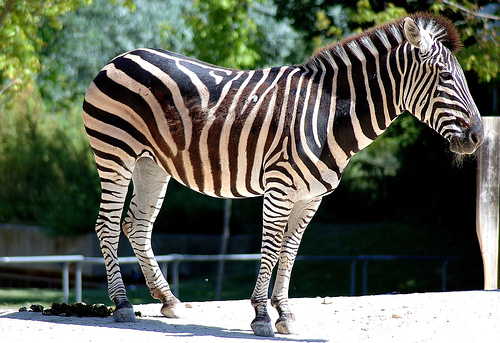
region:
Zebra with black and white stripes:
[79, 8, 486, 339]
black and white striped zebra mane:
[296, 9, 470, 74]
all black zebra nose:
[448, 116, 488, 154]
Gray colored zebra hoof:
[248, 319, 275, 335]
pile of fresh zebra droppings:
[17, 296, 111, 318]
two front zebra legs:
[241, 193, 322, 336]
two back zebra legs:
[88, 156, 192, 321]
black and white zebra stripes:
[106, 67, 227, 127]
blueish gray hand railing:
[0, 252, 84, 299]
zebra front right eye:
[439, 70, 453, 80]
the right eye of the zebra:
[431, 66, 454, 82]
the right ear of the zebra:
[397, 14, 428, 56]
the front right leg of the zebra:
[245, 159, 296, 341]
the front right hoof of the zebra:
[246, 310, 276, 341]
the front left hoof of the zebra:
[272, 310, 304, 341]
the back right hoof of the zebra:
[105, 292, 137, 324]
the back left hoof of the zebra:
[152, 291, 192, 323]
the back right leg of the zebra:
[80, 128, 162, 320]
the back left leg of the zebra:
[120, 140, 200, 320]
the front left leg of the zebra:
[267, 179, 325, 337]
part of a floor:
[333, 291, 363, 331]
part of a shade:
[180, 315, 205, 335]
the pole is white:
[5, 244, 76, 276]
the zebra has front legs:
[247, 212, 297, 337]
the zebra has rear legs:
[89, 177, 183, 329]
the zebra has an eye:
[432, 58, 456, 85]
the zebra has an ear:
[389, 9, 428, 39]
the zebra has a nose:
[463, 122, 482, 152]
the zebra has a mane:
[312, 35, 384, 54]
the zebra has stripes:
[175, 103, 284, 154]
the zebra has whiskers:
[453, 148, 465, 165]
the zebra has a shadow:
[157, 319, 214, 333]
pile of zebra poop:
[15, 294, 115, 321]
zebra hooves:
[109, 295, 309, 340]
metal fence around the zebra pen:
[0, 245, 496, 292]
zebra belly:
[157, 134, 273, 211]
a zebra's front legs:
[242, 192, 328, 342]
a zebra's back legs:
[97, 153, 183, 328]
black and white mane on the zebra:
[305, 8, 459, 78]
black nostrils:
[450, 120, 490, 165]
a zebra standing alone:
[69, 17, 484, 341]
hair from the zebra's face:
[452, 148, 466, 167]